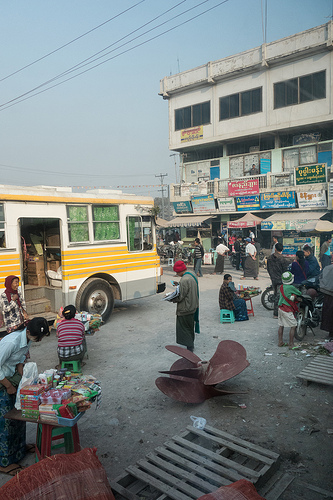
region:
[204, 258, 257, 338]
woman sitting on a stool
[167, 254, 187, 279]
the hat is red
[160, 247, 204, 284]
the hat is red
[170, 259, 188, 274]
the hat is red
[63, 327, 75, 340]
the shirt has stripes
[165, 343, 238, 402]
the fan is onthe ground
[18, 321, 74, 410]
she is looking through the items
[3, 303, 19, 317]
the shirt is plaid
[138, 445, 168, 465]
the wood pallet is on the ground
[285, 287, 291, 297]
the shirt is green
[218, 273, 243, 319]
the girl is sitting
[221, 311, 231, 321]
the stool is blue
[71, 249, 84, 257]
the stripe is yellow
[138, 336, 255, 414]
A large fan blade is lying on the ground.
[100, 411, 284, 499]
A wooden pallet is lying on the ground.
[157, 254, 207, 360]
The man is wearing a cap.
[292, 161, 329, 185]
The sign is green and yellow.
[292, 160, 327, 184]
The sign is rectangular.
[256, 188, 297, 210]
The sign is rectangular.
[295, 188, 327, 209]
The sign is rectangular.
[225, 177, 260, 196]
The sign is rectangular.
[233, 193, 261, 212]
The sign is rectangular.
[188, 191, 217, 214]
The sign is rectangular.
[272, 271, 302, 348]
Child in green and white hat.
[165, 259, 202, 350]
Person wearing a red hat.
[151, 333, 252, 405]
Old rusted propeller on ground.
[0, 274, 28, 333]
Person wearing a red head scarf and checkered shirt.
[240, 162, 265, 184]
Man standing on balcony.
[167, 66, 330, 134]
Six window on building.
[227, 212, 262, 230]
Red and white awning.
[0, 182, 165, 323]
White bus with yellow and blue stripes.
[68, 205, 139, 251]
Green and white curtains on bus.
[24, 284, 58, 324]
Steps to inside of bus.